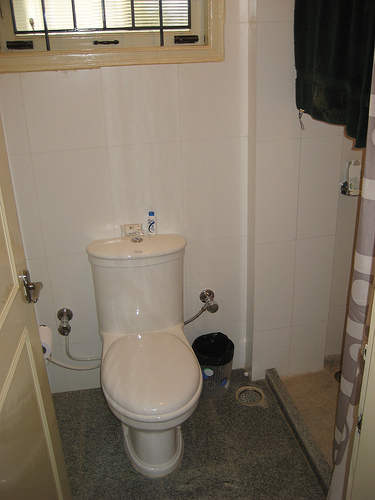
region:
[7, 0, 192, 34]
Black iron bars on window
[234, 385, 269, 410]
Silver metal bathroom floor drain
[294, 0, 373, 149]
Black bath towel hanging over shower rod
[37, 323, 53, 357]
Roll of toilet paper on holder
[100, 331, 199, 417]
White oval toilet lid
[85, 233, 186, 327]
White tank of toile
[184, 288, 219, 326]
Left side plumbing for toilet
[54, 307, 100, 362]
Right sided toilet plumbing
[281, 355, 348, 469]
Tan colored inside of shower floor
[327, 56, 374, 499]
Tan and white patterned shower curtain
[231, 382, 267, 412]
Drain in the bathroom.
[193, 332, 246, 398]
Spotted trash can in the bathroom.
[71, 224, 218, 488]
Toilet in the center of the bathroom.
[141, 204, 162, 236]
Heads and Shoulders bottle on the front.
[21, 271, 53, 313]
Door handle on the door.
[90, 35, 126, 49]
Window handle on the window.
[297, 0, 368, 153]
Towel hanging from the shower.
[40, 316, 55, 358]
Toilet paper in the bathroom.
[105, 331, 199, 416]
White toilet seat on the toilet.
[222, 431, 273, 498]
Tile floor in the bathroom.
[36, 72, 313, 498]
picture taken indoors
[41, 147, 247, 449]
picture of a toilet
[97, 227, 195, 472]
the toilet is white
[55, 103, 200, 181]
the tiles are off white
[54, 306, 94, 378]
the plumbing of the toilet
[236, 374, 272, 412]
a drain on the floor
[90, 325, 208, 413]
the toilet seat is down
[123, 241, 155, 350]
the toilet is shiny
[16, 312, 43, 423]
the door is open to the bathroom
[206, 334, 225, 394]
a trash can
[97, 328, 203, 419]
White lid of closed toilet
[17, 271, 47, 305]
Door knob on bathroom door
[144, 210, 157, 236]
Deodorant on back of toilet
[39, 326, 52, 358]
Bathroom toilet tissue roll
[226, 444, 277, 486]
Multicolored tile on bathroom floor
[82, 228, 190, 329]
White Bathroom toilet tank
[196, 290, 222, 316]
shutoff valve for toilet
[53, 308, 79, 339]
Water source for bathroom toilet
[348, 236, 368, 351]
Part of shower curtain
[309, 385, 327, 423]
Part of bathroom shower floor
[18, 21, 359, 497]
picture taken inside a bathroom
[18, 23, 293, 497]
a plain bathroom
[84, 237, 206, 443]
the toilet is shiny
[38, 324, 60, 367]
toilet paper next to toilet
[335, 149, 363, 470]
a shower curtain next to toilet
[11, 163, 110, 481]
the door to the bathroom is open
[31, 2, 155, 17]
picture taken during the day